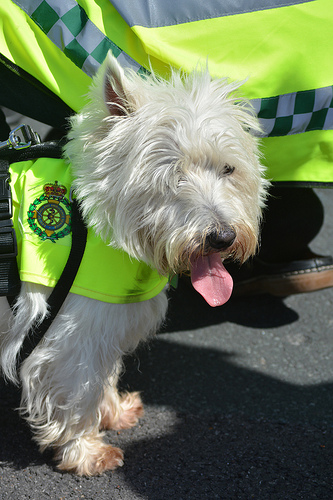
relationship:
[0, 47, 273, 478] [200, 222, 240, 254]
dog has nose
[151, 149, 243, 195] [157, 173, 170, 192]
eyes are covered by fur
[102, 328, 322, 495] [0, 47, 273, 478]
shadow of dog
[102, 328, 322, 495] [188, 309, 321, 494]
shadow on ground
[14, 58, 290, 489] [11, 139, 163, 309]
dog wearing cloth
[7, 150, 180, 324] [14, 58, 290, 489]
back on dog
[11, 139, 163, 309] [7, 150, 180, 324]
cloth on back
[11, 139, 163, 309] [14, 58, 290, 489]
cloth on dog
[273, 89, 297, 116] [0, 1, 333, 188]
square on cloth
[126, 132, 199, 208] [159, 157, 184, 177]
hair cover eye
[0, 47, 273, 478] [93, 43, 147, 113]
dog has ear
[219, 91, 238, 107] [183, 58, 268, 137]
ear under hair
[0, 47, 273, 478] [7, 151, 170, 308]
dog has cloth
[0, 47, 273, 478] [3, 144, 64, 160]
dog has leash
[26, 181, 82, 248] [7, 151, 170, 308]
graphic on cloth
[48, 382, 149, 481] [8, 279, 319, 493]
feet on pavement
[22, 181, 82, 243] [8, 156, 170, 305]
graphic on clothes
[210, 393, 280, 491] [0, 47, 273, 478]
concrete under dog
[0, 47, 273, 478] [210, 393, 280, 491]
dog on concrete